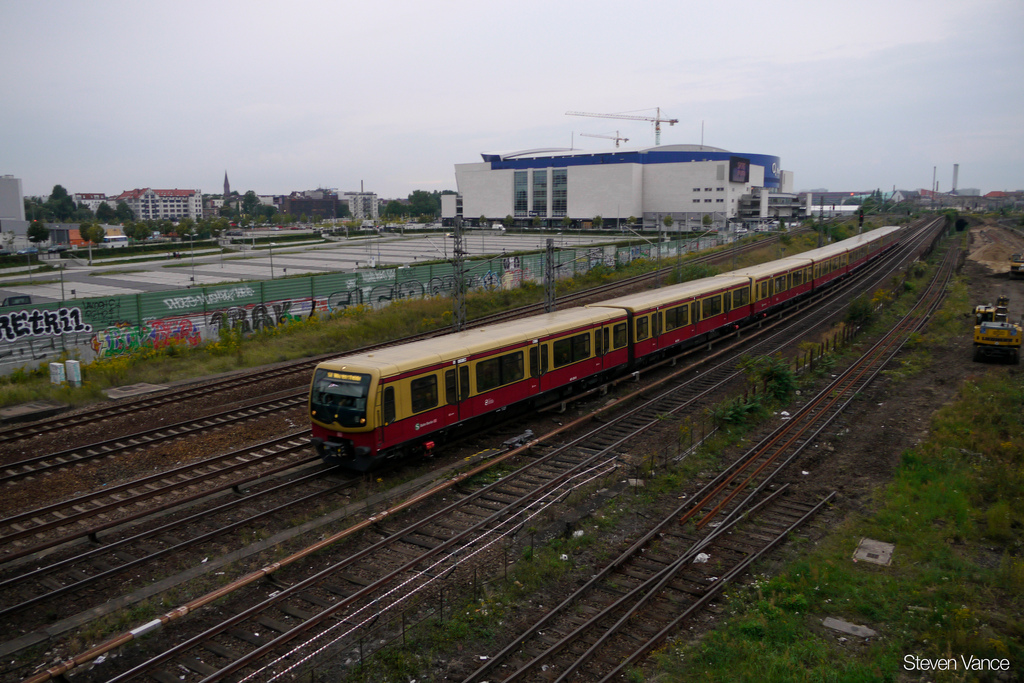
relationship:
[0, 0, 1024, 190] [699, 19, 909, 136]
cloud in sky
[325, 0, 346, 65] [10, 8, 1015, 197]
cloud in sky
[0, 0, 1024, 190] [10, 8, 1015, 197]
cloud in sky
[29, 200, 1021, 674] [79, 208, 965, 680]
vegetation growing between tracks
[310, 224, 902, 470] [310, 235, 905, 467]
train with bottom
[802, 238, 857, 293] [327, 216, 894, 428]
train with top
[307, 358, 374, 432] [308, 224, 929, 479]
window of train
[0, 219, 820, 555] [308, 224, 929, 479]
tracks of train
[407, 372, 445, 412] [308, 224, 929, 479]
window on train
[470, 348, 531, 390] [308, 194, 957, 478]
window on train